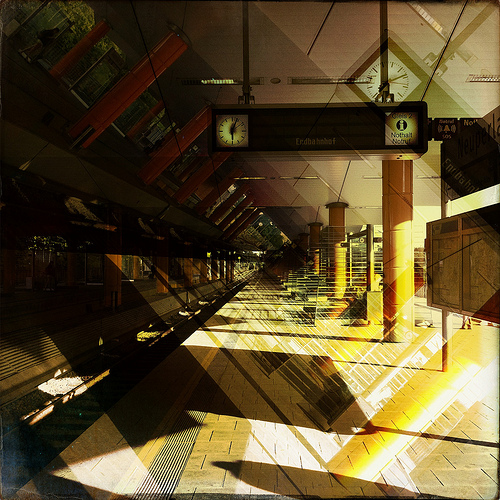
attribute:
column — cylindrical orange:
[352, 154, 437, 351]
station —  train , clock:
[96, 52, 432, 486]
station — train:
[160, 76, 439, 466]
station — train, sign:
[197, 123, 465, 476]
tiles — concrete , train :
[273, 380, 449, 460]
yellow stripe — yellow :
[139, 350, 204, 488]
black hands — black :
[223, 112, 251, 150]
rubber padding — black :
[155, 325, 216, 495]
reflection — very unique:
[224, 295, 457, 498]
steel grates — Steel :
[135, 316, 242, 492]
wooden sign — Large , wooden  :
[409, 207, 498, 318]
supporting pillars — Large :
[273, 191, 442, 323]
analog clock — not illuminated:
[196, 96, 257, 152]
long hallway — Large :
[131, 163, 331, 384]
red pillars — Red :
[39, 20, 211, 213]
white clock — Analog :
[349, 40, 428, 121]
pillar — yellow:
[338, 107, 446, 280]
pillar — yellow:
[291, 109, 473, 373]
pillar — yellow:
[375, 111, 446, 356]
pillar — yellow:
[357, 101, 440, 360]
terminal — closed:
[258, 220, 380, 319]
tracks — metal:
[20, 350, 114, 440]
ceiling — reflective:
[339, 4, 466, 105]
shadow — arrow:
[214, 338, 378, 449]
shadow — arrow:
[264, 292, 352, 396]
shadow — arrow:
[208, 279, 315, 475]